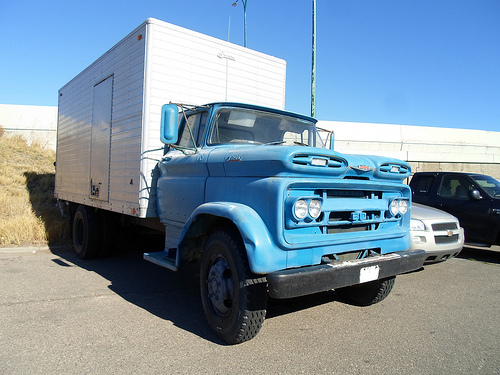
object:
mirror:
[329, 131, 334, 151]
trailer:
[52, 17, 287, 219]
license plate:
[360, 265, 380, 283]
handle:
[160, 156, 171, 161]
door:
[156, 102, 216, 228]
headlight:
[388, 196, 409, 215]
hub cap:
[204, 260, 234, 317]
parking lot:
[9, 239, 499, 374]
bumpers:
[267, 249, 426, 300]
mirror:
[161, 103, 179, 146]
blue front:
[143, 103, 412, 274]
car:
[409, 200, 464, 265]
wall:
[1, 99, 496, 195]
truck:
[407, 162, 493, 257]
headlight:
[291, 197, 323, 220]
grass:
[1, 131, 67, 243]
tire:
[199, 230, 269, 345]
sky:
[2, 1, 499, 133]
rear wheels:
[69, 205, 109, 261]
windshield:
[206, 106, 316, 146]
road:
[8, 242, 498, 373]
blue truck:
[50, 17, 428, 347]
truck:
[410, 169, 498, 261]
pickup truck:
[410, 171, 499, 265]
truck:
[50, 18, 426, 345]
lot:
[328, 310, 410, 354]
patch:
[2, 142, 41, 218]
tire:
[333, 255, 396, 307]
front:
[142, 102, 425, 345]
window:
[167, 113, 198, 153]